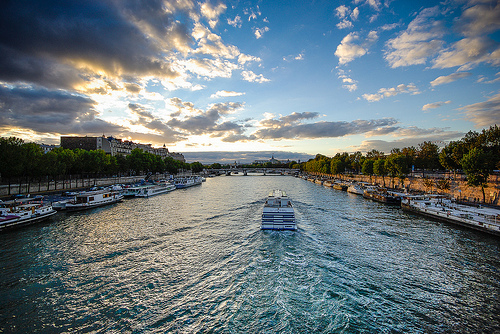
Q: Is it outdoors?
A: Yes, it is outdoors.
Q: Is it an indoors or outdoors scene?
A: It is outdoors.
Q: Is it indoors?
A: No, it is outdoors.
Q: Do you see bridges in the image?
A: Yes, there is a bridge.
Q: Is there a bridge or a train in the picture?
A: Yes, there is a bridge.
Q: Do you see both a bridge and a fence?
A: No, there is a bridge but no fences.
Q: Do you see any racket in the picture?
A: No, there are no rackets.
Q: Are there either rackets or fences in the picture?
A: No, there are no rackets or fences.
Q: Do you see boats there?
A: Yes, there is a boat.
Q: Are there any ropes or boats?
A: Yes, there is a boat.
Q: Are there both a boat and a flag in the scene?
A: No, there is a boat but no flags.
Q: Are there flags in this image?
A: No, there are no flags.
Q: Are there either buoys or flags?
A: No, there are no flags or buoys.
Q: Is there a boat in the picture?
A: Yes, there is a boat.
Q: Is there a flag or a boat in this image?
A: Yes, there is a boat.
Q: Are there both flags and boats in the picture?
A: No, there is a boat but no flags.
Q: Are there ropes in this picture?
A: No, there are no ropes.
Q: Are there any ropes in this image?
A: No, there are no ropes.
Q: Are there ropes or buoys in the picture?
A: No, there are no ropes or buoys.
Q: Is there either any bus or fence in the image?
A: No, there are no fences or buses.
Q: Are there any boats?
A: Yes, there is a boat.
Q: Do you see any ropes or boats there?
A: Yes, there is a boat.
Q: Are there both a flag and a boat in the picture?
A: No, there is a boat but no flags.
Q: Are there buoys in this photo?
A: No, there are no buoys.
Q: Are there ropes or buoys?
A: No, there are no buoys or ropes.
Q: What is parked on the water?
A: The boat is parked on the water.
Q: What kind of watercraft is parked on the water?
A: The watercraft is a boat.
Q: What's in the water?
A: The boat is in the water.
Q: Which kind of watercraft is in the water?
A: The watercraft is a boat.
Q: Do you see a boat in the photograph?
A: Yes, there is a boat.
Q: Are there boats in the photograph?
A: Yes, there is a boat.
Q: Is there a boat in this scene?
A: Yes, there is a boat.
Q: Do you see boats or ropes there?
A: Yes, there is a boat.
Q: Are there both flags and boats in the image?
A: No, there is a boat but no flags.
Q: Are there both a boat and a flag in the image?
A: No, there is a boat but no flags.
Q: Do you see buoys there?
A: No, there are no buoys.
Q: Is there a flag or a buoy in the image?
A: No, there are no buoys or flags.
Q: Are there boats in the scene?
A: Yes, there is a boat.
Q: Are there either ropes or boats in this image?
A: Yes, there is a boat.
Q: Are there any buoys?
A: No, there are no buoys.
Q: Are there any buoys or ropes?
A: No, there are no buoys or ropes.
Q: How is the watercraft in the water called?
A: The watercraft is a boat.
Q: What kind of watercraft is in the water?
A: The watercraft is a boat.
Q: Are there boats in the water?
A: Yes, there is a boat in the water.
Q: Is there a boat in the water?
A: Yes, there is a boat in the water.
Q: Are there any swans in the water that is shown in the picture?
A: No, there is a boat in the water.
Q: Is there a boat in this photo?
A: Yes, there is a boat.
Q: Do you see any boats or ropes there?
A: Yes, there is a boat.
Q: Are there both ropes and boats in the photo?
A: No, there is a boat but no ropes.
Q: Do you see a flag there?
A: No, there are no flags.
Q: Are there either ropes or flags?
A: No, there are no flags or ropes.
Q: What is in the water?
A: The boat is in the water.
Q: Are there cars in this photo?
A: No, there are no cars.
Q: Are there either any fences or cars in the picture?
A: No, there are no cars or fences.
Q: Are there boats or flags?
A: Yes, there is a boat.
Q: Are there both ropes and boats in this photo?
A: No, there is a boat but no ropes.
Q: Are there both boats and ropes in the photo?
A: No, there is a boat but no ropes.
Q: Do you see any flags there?
A: No, there are no flags.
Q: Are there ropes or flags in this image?
A: No, there are no flags or ropes.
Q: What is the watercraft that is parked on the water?
A: The watercraft is a boat.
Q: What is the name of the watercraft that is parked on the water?
A: The watercraft is a boat.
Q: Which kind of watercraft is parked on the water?
A: The watercraft is a boat.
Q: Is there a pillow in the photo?
A: No, there are no pillows.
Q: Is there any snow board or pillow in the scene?
A: No, there are no pillows or snowboards.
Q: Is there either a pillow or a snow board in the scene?
A: No, there are no pillows or snowboards.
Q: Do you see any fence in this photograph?
A: No, there are no fences.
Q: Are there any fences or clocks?
A: No, there are no fences or clocks.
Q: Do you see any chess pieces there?
A: No, there are no chess pieces.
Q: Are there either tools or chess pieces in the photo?
A: No, there are no chess pieces or tools.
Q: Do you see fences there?
A: No, there are no fences.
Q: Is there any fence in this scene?
A: No, there are no fences.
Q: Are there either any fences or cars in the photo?
A: No, there are no cars or fences.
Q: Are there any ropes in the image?
A: No, there are no ropes.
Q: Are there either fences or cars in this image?
A: No, there are no cars or fences.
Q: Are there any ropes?
A: No, there are no ropes.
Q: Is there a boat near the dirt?
A: Yes, there are boats near the dirt.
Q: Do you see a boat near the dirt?
A: Yes, there are boats near the dirt.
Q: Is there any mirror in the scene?
A: No, there are no mirrors.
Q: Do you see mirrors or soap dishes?
A: No, there are no mirrors or soap dishes.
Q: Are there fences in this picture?
A: No, there are no fences.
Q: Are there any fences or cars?
A: No, there are no fences or cars.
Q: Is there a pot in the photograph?
A: No, there are no pots.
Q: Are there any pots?
A: No, there are no pots.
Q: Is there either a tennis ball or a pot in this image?
A: No, there are no pots or tennis balls.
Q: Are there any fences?
A: No, there are no fences.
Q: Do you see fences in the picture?
A: No, there are no fences.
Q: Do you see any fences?
A: No, there are no fences.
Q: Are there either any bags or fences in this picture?
A: No, there are no fences or bags.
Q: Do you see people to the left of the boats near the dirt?
A: Yes, there are people to the left of the boats.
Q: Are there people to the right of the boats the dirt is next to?
A: No, the people are to the left of the boats.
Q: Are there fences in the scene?
A: No, there are no fences.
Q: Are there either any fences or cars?
A: No, there are no fences or cars.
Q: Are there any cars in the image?
A: No, there are no cars.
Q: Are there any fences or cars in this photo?
A: No, there are no cars or fences.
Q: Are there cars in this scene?
A: No, there are no cars.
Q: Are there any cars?
A: No, there are no cars.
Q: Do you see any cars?
A: No, there are no cars.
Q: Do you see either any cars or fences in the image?
A: No, there are no cars or fences.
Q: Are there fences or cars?
A: No, there are no cars or fences.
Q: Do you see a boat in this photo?
A: Yes, there is a boat.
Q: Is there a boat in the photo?
A: Yes, there is a boat.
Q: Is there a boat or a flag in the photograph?
A: Yes, there is a boat.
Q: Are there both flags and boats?
A: No, there is a boat but no flags.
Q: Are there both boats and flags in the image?
A: No, there is a boat but no flags.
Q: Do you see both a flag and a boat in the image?
A: No, there is a boat but no flags.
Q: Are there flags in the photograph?
A: No, there are no flags.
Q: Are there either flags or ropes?
A: No, there are no flags or ropes.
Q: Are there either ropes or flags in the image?
A: No, there are no flags or ropes.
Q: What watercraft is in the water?
A: The watercraft is a boat.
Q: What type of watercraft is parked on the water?
A: The watercraft is a boat.